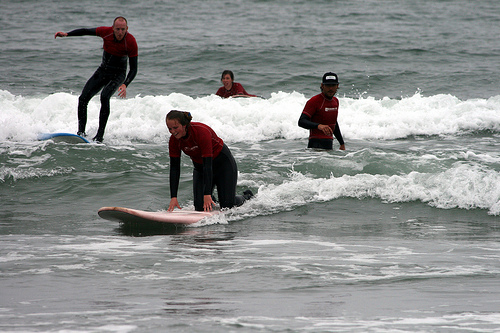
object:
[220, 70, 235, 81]
hair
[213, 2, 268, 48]
water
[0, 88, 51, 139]
sea foam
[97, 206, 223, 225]
surfboard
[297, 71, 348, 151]
man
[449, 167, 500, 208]
wave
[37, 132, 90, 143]
surfboard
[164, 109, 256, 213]
lady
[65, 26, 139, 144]
surf suit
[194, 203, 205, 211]
knees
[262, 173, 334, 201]
waves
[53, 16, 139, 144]
man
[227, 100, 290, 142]
wave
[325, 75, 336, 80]
design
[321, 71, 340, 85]
hat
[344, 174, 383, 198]
waves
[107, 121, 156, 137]
waves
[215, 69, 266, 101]
woman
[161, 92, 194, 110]
wave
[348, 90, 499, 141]
foam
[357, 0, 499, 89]
water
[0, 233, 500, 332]
shallows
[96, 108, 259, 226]
surf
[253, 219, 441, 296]
ocean